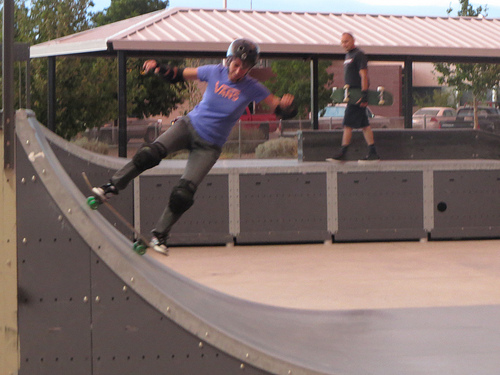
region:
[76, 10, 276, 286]
woman in a blue shirt on a skateboard ramp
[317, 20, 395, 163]
man wearing shorts holding a skateboard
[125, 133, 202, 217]
black skateboarding knee pads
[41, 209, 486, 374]
skate board ramp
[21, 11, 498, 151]
covered pavilion next to skate board ramp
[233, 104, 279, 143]
bed of a red pickup truck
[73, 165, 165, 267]
skate board with green wheels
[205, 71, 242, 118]
logo on woman's shirt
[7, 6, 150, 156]
green trees in the background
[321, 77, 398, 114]
long board with green underside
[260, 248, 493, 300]
The surface is solid white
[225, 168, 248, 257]
large tan line with black base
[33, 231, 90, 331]
black holes on gray base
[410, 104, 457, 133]
white car parked in spot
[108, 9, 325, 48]
pink roof with white stripes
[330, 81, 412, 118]
oblong green skateboard with white wheels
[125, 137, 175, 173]
bulky black knee pad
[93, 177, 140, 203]
white sneakers with black top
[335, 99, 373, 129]
black shorts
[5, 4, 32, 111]
large trees with green leaves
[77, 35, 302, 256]
Person on a skateboard.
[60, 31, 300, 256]
Person wearing a helmet.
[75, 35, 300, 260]
Person wearing knee pads.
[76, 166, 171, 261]
Skateboard with green wheels.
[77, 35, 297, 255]
Person wearing a blue shirt.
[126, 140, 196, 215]
Pair of black knee pads.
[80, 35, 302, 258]
Person wearing black and white shoes.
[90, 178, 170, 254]
Pair of black and white shoes.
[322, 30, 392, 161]
Person wearing black shorts.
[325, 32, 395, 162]
Person holding a skateboard.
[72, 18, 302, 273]
Girl in blue shirt skateboarding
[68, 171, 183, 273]
Skateboard with green wheels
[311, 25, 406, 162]
Man walking with skateboard under arm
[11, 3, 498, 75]
long red metal roof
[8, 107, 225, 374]
Large ramp for skating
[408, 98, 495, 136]
Cars in background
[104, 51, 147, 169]
Long black poles holding up roof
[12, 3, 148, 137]
trees in the background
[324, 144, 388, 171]
black shoes with white soles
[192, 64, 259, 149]
Blue shirt that says Vans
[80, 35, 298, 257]
A person on skateboard.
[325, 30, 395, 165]
A man walking on edge of wall.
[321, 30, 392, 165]
A man carrying skateboard.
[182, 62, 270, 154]
The person's shirt is blue.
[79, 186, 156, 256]
The wheels on skateboard are green.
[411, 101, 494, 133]
Cars in parking lot.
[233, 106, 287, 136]
A red truck.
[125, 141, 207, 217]
The person is wearing knee pads.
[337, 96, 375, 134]
The man is wearing shorts.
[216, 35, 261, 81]
The person is wearing a helmut.